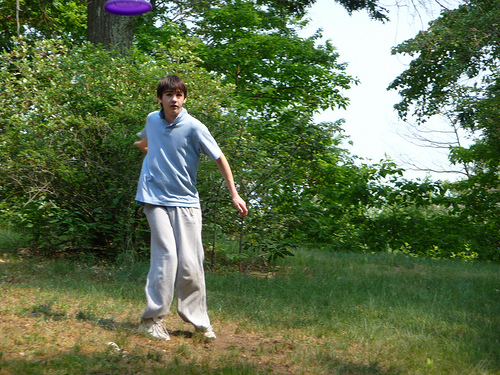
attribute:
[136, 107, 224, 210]
t-shirt — light blue, blue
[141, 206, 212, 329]
pants — gray, lose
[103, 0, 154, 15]
frisbee — purple, blue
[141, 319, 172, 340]
shoe — white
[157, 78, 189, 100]
hair — brown